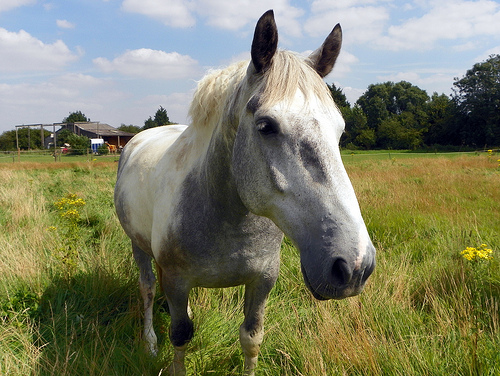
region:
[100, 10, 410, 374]
a horse standing in a field.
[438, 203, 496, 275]
A bunch of yellow flowers.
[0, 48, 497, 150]
a forest of green trees.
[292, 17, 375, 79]
a horses left ear.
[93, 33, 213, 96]
a gray cloud in a blue sky.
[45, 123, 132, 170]
a structure near a forest.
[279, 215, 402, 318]
a white horses nose.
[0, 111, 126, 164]
a wooden structure.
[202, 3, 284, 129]
the side of a horses head.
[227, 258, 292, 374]
the left leg of a horse.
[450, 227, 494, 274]
yellow wildflowers in the grass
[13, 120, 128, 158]
house in the background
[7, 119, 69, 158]
large wooden frame behind house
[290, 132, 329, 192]
dark mark on face of horse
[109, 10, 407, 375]
a white and gray horse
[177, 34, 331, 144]
white mane of horse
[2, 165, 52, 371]
dried grass in the field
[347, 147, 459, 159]
flat green area in background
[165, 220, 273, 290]
chest of the horse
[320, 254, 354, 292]
nostril of the horse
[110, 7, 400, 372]
A white horse in the photo.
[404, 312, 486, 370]
Green grass in the photo.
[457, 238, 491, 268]
Yellow flowers in the photo.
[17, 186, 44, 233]
Dry grass in the photo.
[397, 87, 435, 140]
Trees in the photo.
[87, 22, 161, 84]
A sky with few clouds.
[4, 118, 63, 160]
A structure with wooden poles.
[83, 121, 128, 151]
A house in the photo.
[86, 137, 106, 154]
A blue and white cloth in the photo.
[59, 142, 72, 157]
A red ribbon in the photo.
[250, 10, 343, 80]
Two ears on a horses head.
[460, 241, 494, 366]
Tall flowering weed to the right of a horse.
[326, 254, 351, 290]
Large nostril on a horses nose.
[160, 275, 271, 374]
Two front legs on a horse.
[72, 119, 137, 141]
Slanted gray roof in the distance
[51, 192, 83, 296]
Large yellow weed to the left of a horse.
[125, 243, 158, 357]
A visible back leg of a white horse.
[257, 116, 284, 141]
Dark eye of a white horse.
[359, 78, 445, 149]
Large green trees to the back right of a horse.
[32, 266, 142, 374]
Shadow of a horse in the grass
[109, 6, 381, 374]
white and gray horse in grassy green field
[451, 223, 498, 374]
yellow flowers in field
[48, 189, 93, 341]
yellow flowers growing in field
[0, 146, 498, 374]
large grassy field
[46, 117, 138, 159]
wooden barn next to large field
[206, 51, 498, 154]
row of dark green trees next to field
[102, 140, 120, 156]
brown horse standing near barn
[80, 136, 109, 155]
small blue and white shed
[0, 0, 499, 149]
light blue sky full of fluffy white clouds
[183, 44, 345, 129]
white mane